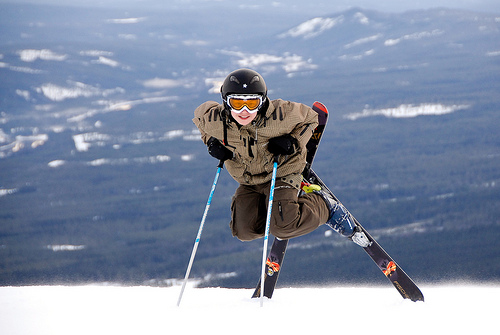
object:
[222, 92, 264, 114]
glasses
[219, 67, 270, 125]
helmet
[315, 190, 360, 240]
boot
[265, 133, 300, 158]
glove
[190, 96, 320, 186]
brown jacket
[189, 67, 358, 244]
woman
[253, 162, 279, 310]
poles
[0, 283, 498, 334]
snow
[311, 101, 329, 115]
tip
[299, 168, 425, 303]
ski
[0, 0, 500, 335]
ground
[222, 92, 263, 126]
head